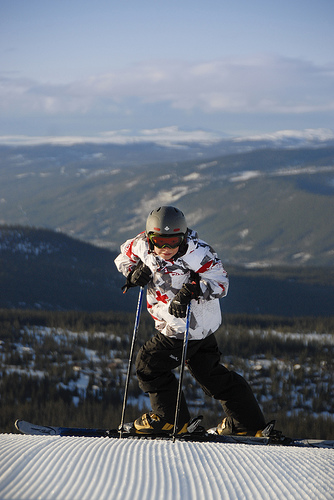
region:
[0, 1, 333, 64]
blue of daytime sky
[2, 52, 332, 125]
clouds low in sky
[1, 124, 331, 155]
snowy mountains on horizons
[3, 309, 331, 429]
snow on ground among trees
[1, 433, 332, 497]
lines on surface of snow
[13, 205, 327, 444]
person standing on skis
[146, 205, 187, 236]
gray helmet on head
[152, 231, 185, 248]
tinted goggles on face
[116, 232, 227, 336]
winter jacket on skier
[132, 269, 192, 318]
gloves on two poles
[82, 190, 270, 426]
this is a boy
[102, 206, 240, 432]
the boy is skating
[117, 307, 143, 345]
this is a stick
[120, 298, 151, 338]
the stick is thin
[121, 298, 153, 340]
the stick is long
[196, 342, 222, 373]
this is a trouser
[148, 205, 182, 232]
this is a helmet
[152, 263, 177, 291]
the jacket is white in color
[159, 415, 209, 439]
these are the skiis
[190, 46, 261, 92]
this is the sky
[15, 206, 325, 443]
person on skis at the top of the slope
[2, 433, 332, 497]
white top of the ski slope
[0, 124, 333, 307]
mountains on the horizon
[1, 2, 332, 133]
partly cloudy sky above the mountains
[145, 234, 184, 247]
the skier's red goggles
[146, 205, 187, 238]
the skier's gray helmet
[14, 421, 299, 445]
snow skis in the snow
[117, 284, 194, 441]
two blue and black ski poles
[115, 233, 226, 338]
the skier's white jacket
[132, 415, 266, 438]
yellow and black ski boots